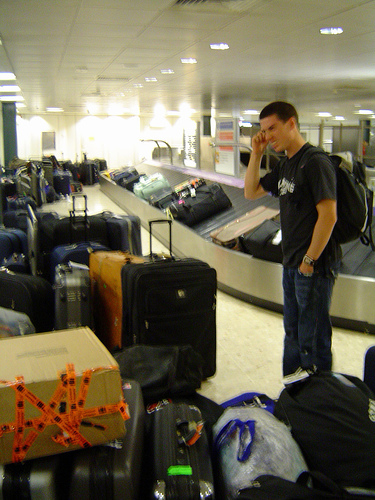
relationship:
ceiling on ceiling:
[121, 31, 193, 83] [121, 49, 193, 84]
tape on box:
[45, 394, 73, 419] [19, 352, 64, 390]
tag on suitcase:
[162, 462, 194, 475] [155, 411, 197, 491]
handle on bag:
[134, 214, 181, 261] [120, 218, 218, 378]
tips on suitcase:
[147, 481, 204, 498] [149, 416, 214, 493]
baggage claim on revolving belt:
[239, 218, 283, 264] [116, 163, 373, 275]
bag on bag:
[208, 391, 314, 498] [213, 388, 309, 497]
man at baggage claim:
[242, 100, 343, 371] [95, 154, 373, 319]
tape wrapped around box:
[0, 362, 130, 463] [2, 324, 128, 463]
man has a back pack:
[242, 100, 343, 371] [322, 150, 369, 245]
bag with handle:
[118, 220, 218, 379] [149, 216, 172, 254]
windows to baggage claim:
[17, 114, 141, 167] [95, 154, 373, 319]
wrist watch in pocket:
[300, 255, 315, 268] [295, 271, 314, 304]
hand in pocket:
[299, 255, 313, 277] [295, 271, 314, 304]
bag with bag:
[213, 388, 309, 497] [208, 391, 314, 498]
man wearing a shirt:
[242, 100, 343, 371] [259, 143, 342, 278]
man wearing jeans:
[242, 100, 343, 371] [281, 244, 338, 375]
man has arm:
[239, 100, 343, 378] [241, 132, 277, 199]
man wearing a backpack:
[242, 100, 343, 371] [322, 146, 371, 249]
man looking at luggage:
[242, 100, 343, 371] [0, 154, 373, 492]